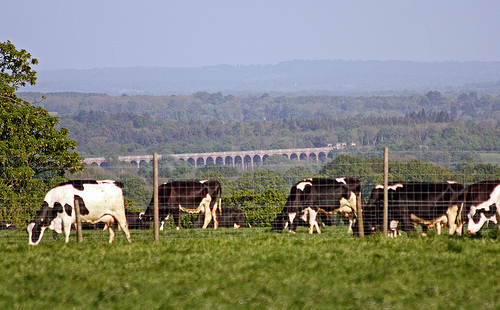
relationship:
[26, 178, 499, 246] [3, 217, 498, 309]
cows eating grass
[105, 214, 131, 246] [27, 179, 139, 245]
legs of cow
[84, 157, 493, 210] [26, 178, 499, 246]
trees behind cows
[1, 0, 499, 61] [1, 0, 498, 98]
fog in distance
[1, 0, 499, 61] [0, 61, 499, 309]
sky above land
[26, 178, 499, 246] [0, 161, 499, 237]
cows behind fence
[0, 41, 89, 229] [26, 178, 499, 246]
tree beside cows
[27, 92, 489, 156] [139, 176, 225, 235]
hill behind cow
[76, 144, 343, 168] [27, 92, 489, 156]
highway in distance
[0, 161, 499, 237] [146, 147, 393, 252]
fence with poles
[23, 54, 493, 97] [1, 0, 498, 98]
mountains in distance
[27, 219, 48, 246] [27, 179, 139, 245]
head of cow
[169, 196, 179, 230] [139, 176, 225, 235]
leg of cow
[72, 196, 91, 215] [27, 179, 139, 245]
spot on cow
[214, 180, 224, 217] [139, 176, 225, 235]
tail of cow